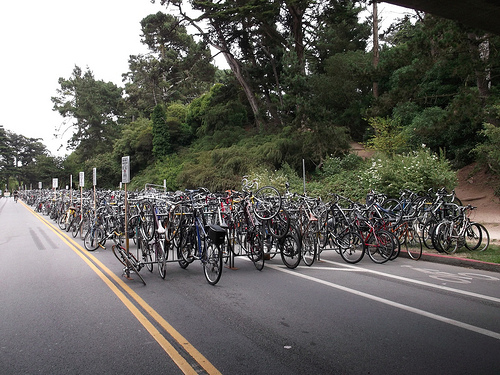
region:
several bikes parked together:
[5, 185, 480, 284]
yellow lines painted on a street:
[47, 220, 197, 374]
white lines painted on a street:
[368, 285, 496, 340]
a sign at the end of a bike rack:
[119, 149, 134, 277]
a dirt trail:
[473, 170, 498, 237]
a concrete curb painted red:
[400, 253, 496, 273]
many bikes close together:
[19, 176, 433, 279]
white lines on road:
[350, 266, 386, 316]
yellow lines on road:
[126, 284, 214, 368]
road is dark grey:
[20, 259, 98, 361]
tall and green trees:
[218, 11, 400, 119]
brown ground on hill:
[427, 170, 489, 225]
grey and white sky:
[19, 16, 88, 103]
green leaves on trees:
[62, 69, 120, 124]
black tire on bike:
[167, 241, 243, 279]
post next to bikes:
[118, 155, 135, 297]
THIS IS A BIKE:
[177, 188, 234, 283]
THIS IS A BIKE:
[225, 189, 288, 221]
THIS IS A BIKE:
[235, 225, 266, 270]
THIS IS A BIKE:
[270, 215, 305, 260]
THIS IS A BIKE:
[309, 214, 367, 257]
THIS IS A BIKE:
[351, 188, 401, 260]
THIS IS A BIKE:
[435, 203, 479, 250]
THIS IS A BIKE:
[82, 214, 102, 256]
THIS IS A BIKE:
[56, 194, 80, 236]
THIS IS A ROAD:
[257, 297, 337, 351]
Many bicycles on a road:
[17, 178, 493, 285]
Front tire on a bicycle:
[202, 245, 229, 285]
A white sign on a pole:
[120, 153, 137, 277]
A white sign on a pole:
[87, 161, 99, 240]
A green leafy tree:
[54, 67, 115, 152]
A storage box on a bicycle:
[204, 223, 225, 242]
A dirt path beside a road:
[449, 154, 494, 246]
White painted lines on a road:
[332, 261, 498, 341]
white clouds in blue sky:
[16, 9, 43, 41]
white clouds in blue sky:
[6, 80, 28, 100]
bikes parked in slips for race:
[135, 210, 161, 260]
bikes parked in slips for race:
[272, 212, 305, 260]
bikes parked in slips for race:
[315, 197, 346, 242]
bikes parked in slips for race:
[373, 202, 396, 252]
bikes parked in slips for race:
[438, 176, 458, 237]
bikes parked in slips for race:
[123, 204, 155, 259]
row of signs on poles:
[23, 153, 130, 266]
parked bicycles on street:
[1, 181, 483, 373]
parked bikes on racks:
[18, 184, 493, 286]